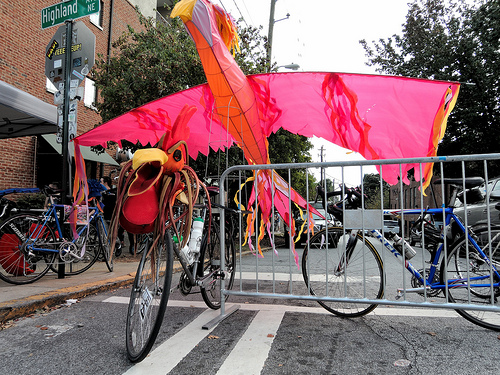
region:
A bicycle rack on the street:
[218, 152, 498, 313]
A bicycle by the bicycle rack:
[300, 176, 498, 331]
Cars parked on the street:
[382, 178, 497, 250]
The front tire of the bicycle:
[125, 223, 174, 360]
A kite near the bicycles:
[74, 0, 475, 260]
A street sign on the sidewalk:
[41, 1, 101, 278]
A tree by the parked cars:
[361, 2, 498, 186]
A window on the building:
[85, 77, 97, 104]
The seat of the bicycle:
[436, 175, 484, 187]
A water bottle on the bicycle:
[390, 230, 417, 260]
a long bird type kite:
[169, 0, 312, 232]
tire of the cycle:
[111, 265, 213, 373]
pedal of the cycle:
[183, 255, 244, 291]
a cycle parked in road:
[261, 185, 493, 313]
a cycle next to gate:
[291, 210, 493, 320]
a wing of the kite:
[276, 21, 451, 216]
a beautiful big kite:
[38, 5, 492, 280]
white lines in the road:
[202, 298, 311, 374]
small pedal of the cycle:
[48, 234, 93, 274]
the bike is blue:
[57, 201, 91, 240]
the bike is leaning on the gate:
[398, 200, 473, 259]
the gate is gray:
[258, 168, 325, 242]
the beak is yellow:
[143, 152, 163, 162]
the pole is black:
[60, 133, 70, 167]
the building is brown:
[10, 22, 42, 77]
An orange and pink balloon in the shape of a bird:
[75, 0, 460, 240]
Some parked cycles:
[5, 178, 499, 361]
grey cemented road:
[0, 208, 498, 374]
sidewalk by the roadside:
[0, 249, 254, 321]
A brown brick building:
[1, 3, 173, 198]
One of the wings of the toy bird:
[249, 73, 459, 193]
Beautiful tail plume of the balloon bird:
[246, 169, 324, 259]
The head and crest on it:
[171, 0, 237, 47]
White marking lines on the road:
[104, 270, 498, 373]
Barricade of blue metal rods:
[218, 153, 498, 313]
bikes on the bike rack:
[105, 138, 496, 343]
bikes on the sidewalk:
[3, 180, 141, 282]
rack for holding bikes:
[218, 150, 499, 321]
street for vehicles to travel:
[241, 258, 484, 355]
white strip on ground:
[148, 273, 474, 370]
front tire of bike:
[292, 230, 389, 312]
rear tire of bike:
[192, 226, 254, 307]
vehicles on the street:
[289, 190, 342, 241]